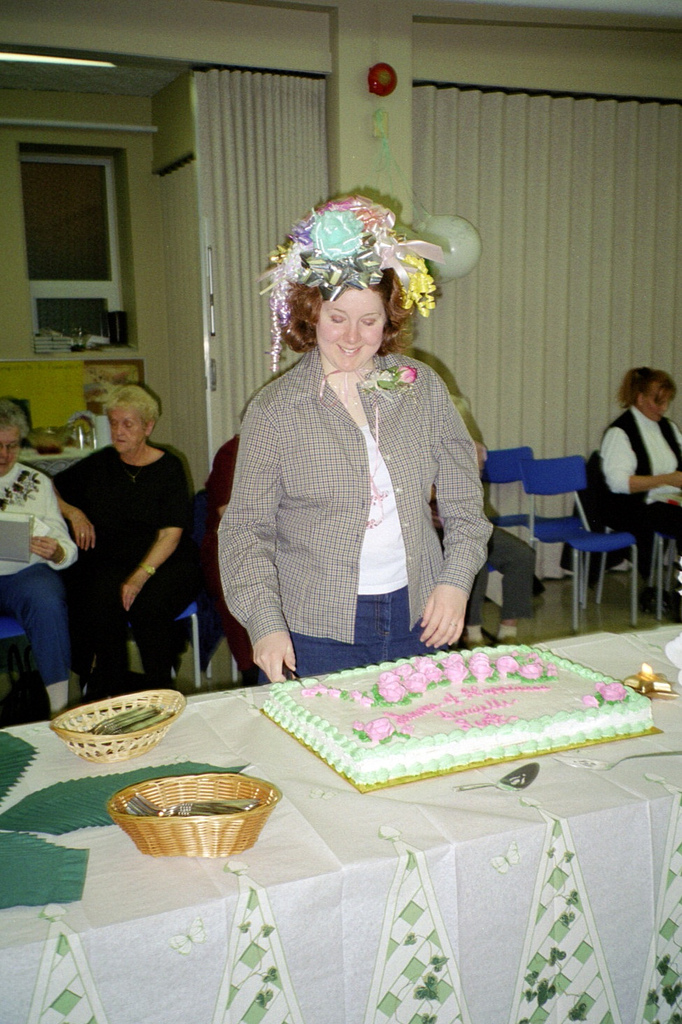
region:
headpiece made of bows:
[254, 178, 445, 372]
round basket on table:
[97, 764, 279, 861]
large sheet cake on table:
[245, 634, 661, 798]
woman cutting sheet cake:
[222, 194, 501, 698]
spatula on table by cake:
[446, 758, 539, 809]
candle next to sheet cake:
[612, 660, 679, 703]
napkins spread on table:
[2, 747, 249, 837]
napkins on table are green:
[4, 752, 255, 836]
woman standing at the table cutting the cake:
[217, 200, 495, 681]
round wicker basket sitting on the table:
[113, 771, 284, 856]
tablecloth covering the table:
[0, 626, 680, 1021]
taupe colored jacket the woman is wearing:
[219, 354, 493, 646]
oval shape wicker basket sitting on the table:
[46, 686, 187, 764]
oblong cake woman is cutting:
[256, 638, 665, 789]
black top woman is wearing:
[55, 435, 192, 560]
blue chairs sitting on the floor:
[484, 441, 638, 631]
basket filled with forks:
[105, 763, 279, 863]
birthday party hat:
[248, 184, 449, 329]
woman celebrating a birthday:
[219, 193, 494, 685]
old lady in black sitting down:
[45, 373, 198, 693]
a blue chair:
[518, 449, 646, 625]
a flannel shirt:
[208, 330, 497, 657]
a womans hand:
[406, 580, 479, 659]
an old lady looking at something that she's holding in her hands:
[0, 379, 79, 724]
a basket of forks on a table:
[102, 769, 291, 860]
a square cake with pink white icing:
[271, 642, 665, 792]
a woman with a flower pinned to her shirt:
[366, 356, 426, 403]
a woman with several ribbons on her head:
[278, 174, 439, 301]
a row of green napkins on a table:
[2, 776, 77, 922]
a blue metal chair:
[527, 459, 632, 631]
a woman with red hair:
[293, 266, 414, 362]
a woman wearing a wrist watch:
[136, 558, 163, 577]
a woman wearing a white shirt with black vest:
[610, 409, 677, 509]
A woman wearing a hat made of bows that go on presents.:
[209, 190, 512, 675]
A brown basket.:
[107, 776, 275, 851]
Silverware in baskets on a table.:
[53, 686, 289, 866]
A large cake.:
[263, 650, 678, 816]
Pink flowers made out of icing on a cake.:
[305, 633, 630, 745]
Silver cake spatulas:
[458, 749, 675, 803]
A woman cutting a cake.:
[237, 228, 572, 739]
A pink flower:
[348, 363, 422, 409]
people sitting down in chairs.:
[0, 358, 675, 713]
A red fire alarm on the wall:
[364, 46, 401, 95]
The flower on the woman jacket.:
[364, 361, 415, 397]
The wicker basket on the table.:
[100, 774, 279, 871]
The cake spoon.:
[450, 756, 550, 796]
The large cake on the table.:
[269, 642, 650, 793]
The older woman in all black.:
[47, 380, 199, 694]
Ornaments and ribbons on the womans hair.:
[249, 211, 429, 339]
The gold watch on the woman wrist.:
[137, 558, 161, 580]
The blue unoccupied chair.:
[502, 435, 629, 604]